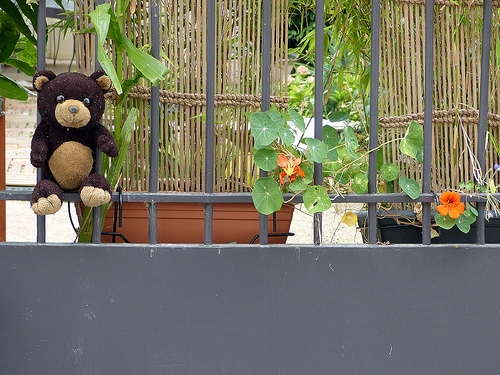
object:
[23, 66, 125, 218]
teddy bear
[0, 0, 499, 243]
fence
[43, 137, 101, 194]
brown tummy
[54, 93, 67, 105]
eye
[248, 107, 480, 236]
plant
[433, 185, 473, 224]
flower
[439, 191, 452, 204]
orange petal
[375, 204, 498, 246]
flower box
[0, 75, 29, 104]
leaf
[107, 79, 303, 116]
rope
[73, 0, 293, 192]
wood sticks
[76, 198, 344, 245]
clay pot